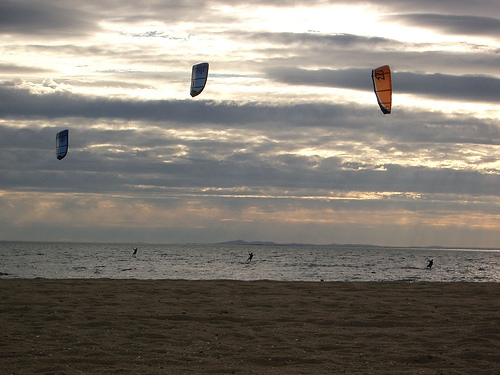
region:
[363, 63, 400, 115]
kite in the sky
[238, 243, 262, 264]
person in the water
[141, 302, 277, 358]
the sand is brown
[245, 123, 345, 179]
clouds in the sky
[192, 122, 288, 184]
the clouds are white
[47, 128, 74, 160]
kite in the air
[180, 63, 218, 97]
the kite is high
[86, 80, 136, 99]
light in the sky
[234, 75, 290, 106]
the sunlight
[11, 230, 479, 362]
water and sand on a beach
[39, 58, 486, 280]
persons with sails in the water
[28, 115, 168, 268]
person with sail on left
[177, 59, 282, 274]
person with sail in middle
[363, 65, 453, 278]
person with sail on right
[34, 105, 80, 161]
blue sail in the air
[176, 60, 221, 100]
blue sail in the air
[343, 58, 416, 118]
reddish sail in the air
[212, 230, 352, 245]
land in the distance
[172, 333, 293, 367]
pits in the sand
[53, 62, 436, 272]
Three people in the water are controlling sails in the sky.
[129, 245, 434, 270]
Three people in the water have extended right arms.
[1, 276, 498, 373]
Sand is white with footprints in it.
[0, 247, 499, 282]
The water is choppy.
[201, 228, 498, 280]
Land is near the horizon.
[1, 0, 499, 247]
The sky has many clouds and shows little sun.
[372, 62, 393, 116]
A sail is orange.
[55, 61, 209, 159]
Two sails are blue and yellow.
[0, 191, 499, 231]
Orange light is shining through a layer of clouds.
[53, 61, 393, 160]
Three sails are flying through the air.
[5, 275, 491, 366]
rippled surface of sand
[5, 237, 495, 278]
surfers on calm gray ocean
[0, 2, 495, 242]
alternating bright and dark streaks in sky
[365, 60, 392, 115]
orange triangular shaped kite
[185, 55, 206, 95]
blue with dark horizontally striped kite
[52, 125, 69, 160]
kite identical to another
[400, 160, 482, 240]
vertical rays from sky to ocean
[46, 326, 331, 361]
light colored dots over sand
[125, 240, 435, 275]
lifted arms on tiny figures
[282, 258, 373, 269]
line of circles across the water